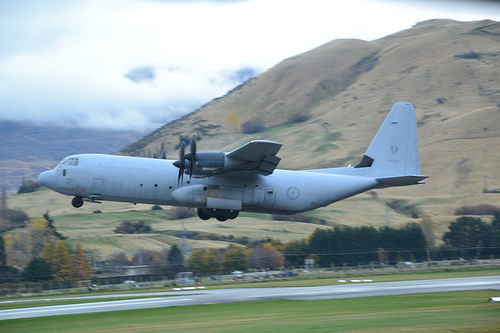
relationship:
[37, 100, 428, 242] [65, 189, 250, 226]
plane has wheels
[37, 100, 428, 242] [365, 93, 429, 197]
plane has tail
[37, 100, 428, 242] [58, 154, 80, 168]
plane has windshield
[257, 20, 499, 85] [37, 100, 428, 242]
mountain behind plane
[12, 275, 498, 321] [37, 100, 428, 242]
runway under plane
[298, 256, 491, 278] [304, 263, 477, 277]
fence in a line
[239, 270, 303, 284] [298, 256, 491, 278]
cars are behind fence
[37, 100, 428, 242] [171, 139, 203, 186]
plane has propellers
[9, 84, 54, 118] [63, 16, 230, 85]
sky has clouds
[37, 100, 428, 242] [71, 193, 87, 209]
plane has front tire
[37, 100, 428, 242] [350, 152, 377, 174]
plane has black area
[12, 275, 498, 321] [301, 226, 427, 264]
runway beside trees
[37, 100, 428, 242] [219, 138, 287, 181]
plane has wing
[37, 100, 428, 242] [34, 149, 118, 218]
plane has front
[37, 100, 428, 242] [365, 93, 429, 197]
plane has tail end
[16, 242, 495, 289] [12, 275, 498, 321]
power lines are alongside airstrip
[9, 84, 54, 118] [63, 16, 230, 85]
sky full of clouds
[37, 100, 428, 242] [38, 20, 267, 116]
plane in air